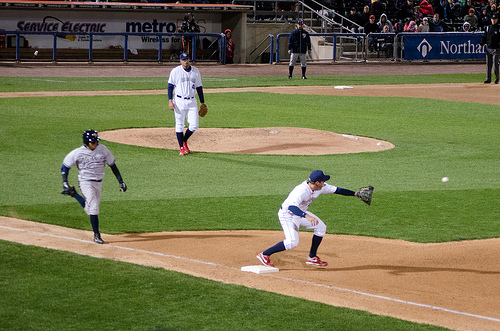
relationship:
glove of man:
[350, 169, 410, 224] [252, 169, 373, 268]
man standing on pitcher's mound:
[252, 169, 373, 268] [88, 106, 399, 168]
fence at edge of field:
[3, 27, 484, 70] [3, 57, 499, 126]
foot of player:
[256, 252, 276, 269] [222, 145, 382, 318]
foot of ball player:
[256, 252, 276, 269] [248, 165, 380, 278]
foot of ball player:
[256, 252, 276, 269] [56, 123, 126, 246]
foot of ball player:
[256, 252, 276, 269] [163, 50, 212, 165]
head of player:
[84, 126, 101, 153] [57, 128, 127, 241]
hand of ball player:
[166, 95, 174, 110] [254, 167, 378, 288]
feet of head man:
[175, 137, 190, 159] [55, 129, 129, 245]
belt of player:
[178, 90, 200, 102] [167, 42, 213, 156]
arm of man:
[192, 82, 208, 114] [165, 50, 205, 155]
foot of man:
[252, 236, 284, 271] [267, 155, 350, 262]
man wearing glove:
[252, 169, 373, 268] [354, 185, 375, 206]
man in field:
[252, 169, 373, 268] [0, 62, 500, 331]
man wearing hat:
[260, 171, 370, 257] [308, 169, 330, 179]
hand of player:
[303, 212, 320, 227] [256, 169, 373, 273]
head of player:
[173, 49, 197, 72] [164, 48, 214, 157]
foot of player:
[256, 252, 276, 269] [263, 160, 356, 263]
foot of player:
[256, 252, 276, 269] [49, 125, 130, 251]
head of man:
[82, 132, 102, 144] [55, 126, 122, 247]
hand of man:
[303, 214, 320, 226] [57, 119, 133, 249]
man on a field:
[252, 169, 373, 268] [4, 59, 496, 326]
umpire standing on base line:
[475, 12, 498, 85] [6, 74, 498, 99]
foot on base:
[256, 252, 276, 269] [233, 255, 282, 282]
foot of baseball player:
[256, 252, 276, 269] [253, 175, 367, 265]